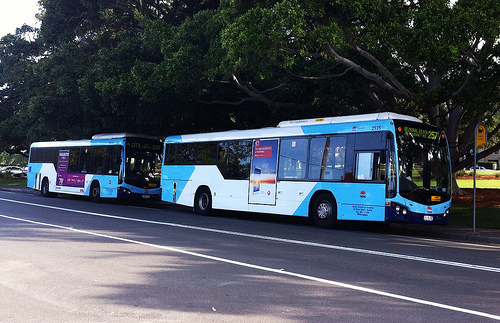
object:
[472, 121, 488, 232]
pole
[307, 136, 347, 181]
window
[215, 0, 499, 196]
trees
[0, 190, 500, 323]
pavement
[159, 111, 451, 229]
bus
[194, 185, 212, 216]
tire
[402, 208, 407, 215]
headlight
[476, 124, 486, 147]
sign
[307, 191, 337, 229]
tire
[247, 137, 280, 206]
ad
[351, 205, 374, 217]
lettering